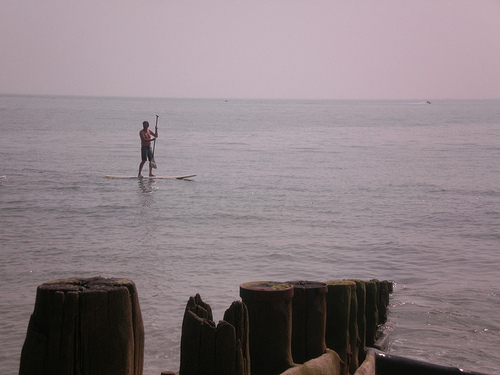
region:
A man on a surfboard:
[137, 110, 160, 185]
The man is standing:
[135, 112, 160, 182]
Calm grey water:
[0, 95, 497, 287]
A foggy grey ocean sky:
[2, 3, 495, 94]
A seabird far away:
[425, 96, 436, 108]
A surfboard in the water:
[98, 171, 207, 185]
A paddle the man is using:
[150, 110, 158, 187]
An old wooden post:
[19, 279, 154, 371]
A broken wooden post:
[180, 285, 244, 373]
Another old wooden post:
[238, 283, 296, 373]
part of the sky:
[320, 19, 415, 83]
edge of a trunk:
[46, 262, 106, 316]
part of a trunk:
[263, 298, 292, 340]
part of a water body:
[420, 197, 481, 269]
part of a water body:
[400, 198, 455, 253]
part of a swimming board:
[171, 156, 196, 188]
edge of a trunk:
[90, 324, 137, 368]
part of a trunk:
[176, 276, 221, 334]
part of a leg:
[136, 164, 146, 170]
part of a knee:
[139, 159, 157, 166]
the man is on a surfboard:
[99, 85, 211, 202]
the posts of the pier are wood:
[40, 259, 138, 366]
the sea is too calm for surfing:
[73, 104, 321, 254]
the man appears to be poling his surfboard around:
[93, 103, 220, 215]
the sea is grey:
[304, 132, 409, 224]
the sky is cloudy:
[257, 19, 344, 71]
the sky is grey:
[222, 9, 384, 70]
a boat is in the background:
[418, 87, 436, 114]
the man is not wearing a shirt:
[127, 95, 179, 195]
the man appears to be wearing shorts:
[126, 108, 175, 219]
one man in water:
[92, 112, 208, 212]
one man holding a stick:
[120, 118, 213, 200]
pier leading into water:
[36, 263, 411, 349]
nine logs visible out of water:
[12, 245, 412, 370]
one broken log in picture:
[6, 232, 397, 348]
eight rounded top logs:
[30, 238, 396, 371]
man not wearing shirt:
[87, 110, 223, 212]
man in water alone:
[118, 115, 223, 206]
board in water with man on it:
[100, 146, 210, 203]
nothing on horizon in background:
[0, 54, 482, 193]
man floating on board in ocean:
[56, 48, 398, 255]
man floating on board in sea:
[80, 70, 287, 230]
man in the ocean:
[77, 51, 329, 230]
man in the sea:
[89, 72, 282, 223]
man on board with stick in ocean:
[89, 65, 289, 240]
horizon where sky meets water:
[206, 57, 363, 187]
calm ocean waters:
[81, 82, 293, 214]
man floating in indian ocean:
[88, 72, 310, 249]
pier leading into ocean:
[158, 220, 442, 370]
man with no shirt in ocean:
[128, 88, 225, 214]